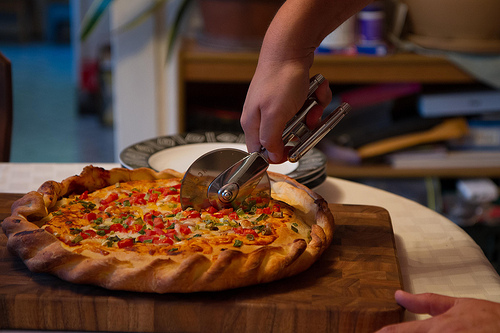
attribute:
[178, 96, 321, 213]
pizza cutter — used for pizza, stainless steel, also pizza slicer, made of metal, shiny, silver colored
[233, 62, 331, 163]
hand — gripping handle, part of person, of a man, masculine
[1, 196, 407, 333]
cutting board — also chopping board, brown, dark brown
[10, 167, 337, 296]
pizza — a supreme pizza, for dinner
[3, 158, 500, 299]
table — white, full, holding plates, holding board, holding pizza, covered with cloth, a light color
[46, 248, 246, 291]
crust — twisted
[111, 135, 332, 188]
stack of plates — three plates